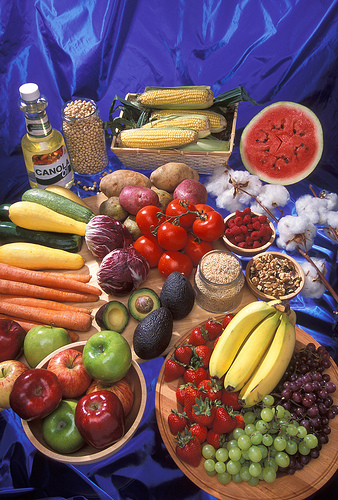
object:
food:
[157, 216, 190, 254]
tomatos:
[133, 231, 160, 270]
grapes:
[260, 403, 277, 425]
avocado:
[126, 286, 163, 322]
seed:
[135, 294, 153, 314]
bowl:
[242, 248, 305, 306]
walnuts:
[251, 275, 260, 287]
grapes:
[279, 388, 292, 403]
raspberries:
[249, 228, 262, 242]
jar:
[61, 95, 108, 178]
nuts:
[74, 135, 79, 148]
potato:
[118, 183, 163, 217]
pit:
[136, 295, 155, 315]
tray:
[152, 309, 338, 498]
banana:
[207, 298, 273, 382]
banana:
[222, 314, 279, 394]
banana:
[238, 309, 296, 414]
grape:
[202, 443, 217, 459]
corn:
[134, 81, 213, 112]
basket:
[110, 90, 239, 177]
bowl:
[20, 339, 148, 468]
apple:
[9, 365, 62, 421]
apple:
[42, 397, 87, 455]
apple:
[73, 388, 127, 452]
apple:
[81, 329, 132, 382]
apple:
[47, 348, 93, 400]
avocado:
[133, 306, 174, 360]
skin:
[131, 305, 174, 360]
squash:
[0, 221, 83, 253]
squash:
[0, 241, 87, 269]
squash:
[9, 200, 88, 239]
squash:
[21, 188, 97, 225]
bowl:
[221, 208, 277, 258]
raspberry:
[245, 220, 254, 229]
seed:
[271, 124, 276, 129]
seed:
[302, 142, 304, 146]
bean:
[76, 112, 81, 113]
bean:
[84, 145, 88, 146]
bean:
[72, 109, 76, 114]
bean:
[85, 105, 91, 113]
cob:
[134, 92, 142, 100]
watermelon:
[237, 100, 325, 191]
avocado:
[93, 298, 130, 333]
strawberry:
[188, 325, 207, 345]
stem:
[174, 425, 192, 446]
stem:
[169, 353, 187, 366]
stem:
[175, 341, 191, 347]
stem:
[200, 326, 209, 340]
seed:
[255, 138, 259, 142]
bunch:
[208, 296, 297, 408]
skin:
[62, 370, 82, 392]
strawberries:
[175, 430, 204, 469]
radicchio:
[96, 244, 150, 298]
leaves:
[97, 247, 128, 283]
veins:
[85, 229, 112, 236]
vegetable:
[1, 261, 103, 296]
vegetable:
[97, 193, 128, 226]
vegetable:
[148, 161, 194, 192]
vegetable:
[84, 215, 125, 259]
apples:
[84, 377, 134, 424]